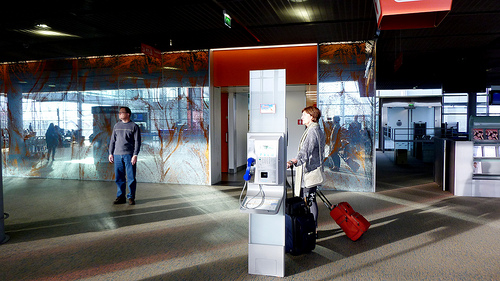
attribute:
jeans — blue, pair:
[110, 154, 136, 202]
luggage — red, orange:
[327, 201, 373, 243]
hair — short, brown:
[300, 103, 321, 124]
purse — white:
[301, 167, 324, 188]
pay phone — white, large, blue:
[246, 135, 287, 193]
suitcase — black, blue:
[284, 194, 319, 259]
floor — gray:
[7, 147, 497, 278]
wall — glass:
[0, 39, 379, 192]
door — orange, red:
[218, 88, 235, 181]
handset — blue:
[245, 156, 257, 183]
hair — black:
[117, 106, 132, 124]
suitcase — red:
[315, 183, 371, 242]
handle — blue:
[240, 153, 255, 184]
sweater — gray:
[294, 125, 325, 181]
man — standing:
[111, 105, 143, 206]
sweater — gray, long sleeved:
[109, 120, 142, 160]